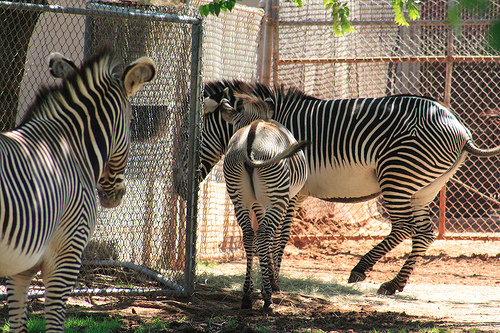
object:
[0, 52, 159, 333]
zebra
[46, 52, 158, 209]
head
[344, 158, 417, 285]
legs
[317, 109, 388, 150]
skin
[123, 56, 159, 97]
ear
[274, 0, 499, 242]
fence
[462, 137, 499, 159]
tail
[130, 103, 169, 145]
window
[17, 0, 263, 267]
wall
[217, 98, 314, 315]
zebras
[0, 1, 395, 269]
enclosure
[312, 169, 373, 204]
belly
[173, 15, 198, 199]
chain link fence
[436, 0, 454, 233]
pole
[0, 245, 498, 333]
ground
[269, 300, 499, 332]
shadow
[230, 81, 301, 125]
neck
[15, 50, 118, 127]
mane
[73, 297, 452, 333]
dirt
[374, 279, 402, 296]
hooves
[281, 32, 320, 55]
sun reflection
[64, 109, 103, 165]
stripes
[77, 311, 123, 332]
grass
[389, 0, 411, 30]
leaf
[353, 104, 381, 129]
fur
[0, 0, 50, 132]
tree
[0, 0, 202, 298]
pen